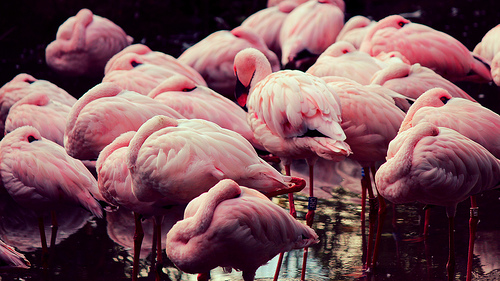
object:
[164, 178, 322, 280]
bird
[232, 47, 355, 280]
bird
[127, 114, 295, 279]
bird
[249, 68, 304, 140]
wing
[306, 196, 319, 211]
tag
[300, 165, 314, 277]
leg